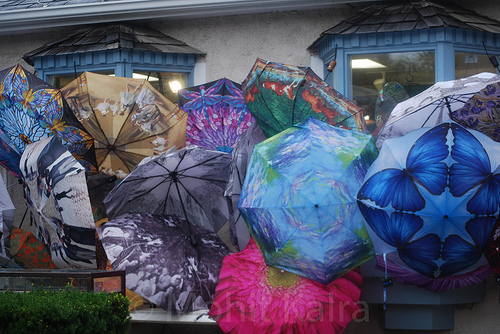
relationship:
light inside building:
[341, 52, 391, 83] [0, 0, 492, 333]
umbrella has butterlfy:
[354, 118, 498, 278] [354, 121, 451, 212]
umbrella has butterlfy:
[354, 118, 498, 278] [447, 122, 499, 217]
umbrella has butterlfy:
[354, 118, 498, 278] [437, 214, 499, 279]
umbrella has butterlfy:
[354, 118, 498, 278] [354, 198, 444, 278]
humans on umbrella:
[87, 81, 163, 130] [58, 68, 189, 179]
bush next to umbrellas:
[1, 287, 133, 332] [2, 55, 495, 327]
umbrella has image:
[57, 180, 247, 315] [112, 230, 177, 296]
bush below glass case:
[1, 287, 133, 332] [0, 259, 134, 297]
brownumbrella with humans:
[62, 67, 188, 184] [87, 81, 163, 130]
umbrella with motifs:
[354, 118, 498, 278] [354, 121, 499, 279]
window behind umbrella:
[348, 37, 423, 97] [376, 144, 454, 251]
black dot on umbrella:
[438, 204, 453, 224] [354, 118, 498, 278]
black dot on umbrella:
[101, 138, 119, 155] [58, 68, 189, 179]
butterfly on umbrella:
[361, 163, 453, 213] [366, 127, 455, 218]